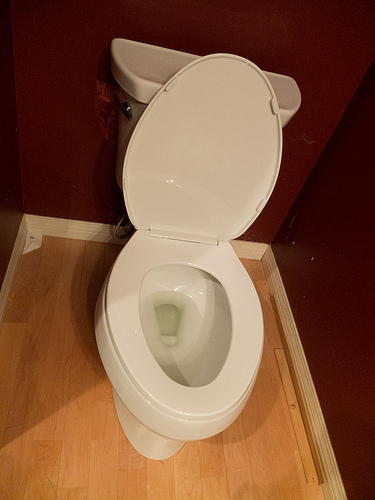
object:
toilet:
[91, 37, 300, 460]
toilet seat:
[103, 229, 266, 420]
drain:
[151, 297, 185, 340]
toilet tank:
[106, 35, 301, 199]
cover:
[106, 39, 299, 242]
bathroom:
[0, 1, 375, 500]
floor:
[1, 208, 375, 499]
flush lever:
[111, 88, 133, 124]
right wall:
[0, 2, 25, 295]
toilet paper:
[19, 224, 45, 257]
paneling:
[0, 211, 348, 500]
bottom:
[109, 382, 188, 464]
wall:
[15, 0, 375, 500]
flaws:
[93, 77, 121, 140]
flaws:
[287, 128, 319, 154]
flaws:
[285, 208, 316, 310]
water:
[143, 286, 201, 360]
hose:
[111, 207, 134, 238]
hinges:
[159, 77, 180, 101]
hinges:
[267, 95, 282, 119]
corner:
[15, 208, 54, 264]